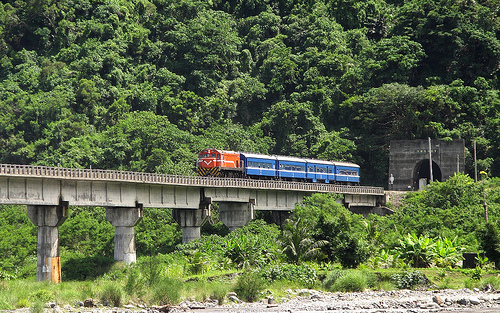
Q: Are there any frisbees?
A: No, there are no frisbees.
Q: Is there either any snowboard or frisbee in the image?
A: No, there are no frisbees or snowboards.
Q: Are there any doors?
A: Yes, there is a door.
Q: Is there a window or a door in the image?
A: Yes, there is a door.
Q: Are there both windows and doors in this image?
A: Yes, there are both a door and a window.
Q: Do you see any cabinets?
A: No, there are no cabinets.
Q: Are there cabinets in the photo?
A: No, there are no cabinets.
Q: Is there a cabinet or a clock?
A: No, there are no cabinets or clocks.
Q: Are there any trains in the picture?
A: Yes, there is a train.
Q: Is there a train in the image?
A: Yes, there is a train.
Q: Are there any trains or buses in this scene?
A: Yes, there is a train.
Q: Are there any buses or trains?
A: Yes, there is a train.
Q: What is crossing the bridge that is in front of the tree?
A: The train is crossing the bridge.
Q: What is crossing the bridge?
A: The train is crossing the bridge.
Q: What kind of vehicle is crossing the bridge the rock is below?
A: The vehicle is a train.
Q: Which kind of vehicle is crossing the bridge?
A: The vehicle is a train.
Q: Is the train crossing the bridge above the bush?
A: Yes, the train is crossing the bridge.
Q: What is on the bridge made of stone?
A: The train is on the bridge.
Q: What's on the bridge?
A: The train is on the bridge.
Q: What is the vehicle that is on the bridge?
A: The vehicle is a train.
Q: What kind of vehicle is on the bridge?
A: The vehicle is a train.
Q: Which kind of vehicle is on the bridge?
A: The vehicle is a train.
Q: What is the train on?
A: The train is on the bridge.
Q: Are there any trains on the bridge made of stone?
A: Yes, there is a train on the bridge.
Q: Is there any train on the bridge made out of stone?
A: Yes, there is a train on the bridge.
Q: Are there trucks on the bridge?
A: No, there is a train on the bridge.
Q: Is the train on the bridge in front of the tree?
A: Yes, the train is on the bridge.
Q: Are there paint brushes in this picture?
A: No, there are no paint brushes.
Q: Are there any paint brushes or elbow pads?
A: No, there are no paint brushes or elbow pads.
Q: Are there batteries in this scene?
A: No, there are no batteries.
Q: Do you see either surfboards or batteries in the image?
A: No, there are no batteries or surfboards.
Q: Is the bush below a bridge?
A: Yes, the bush is below a bridge.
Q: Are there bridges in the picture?
A: Yes, there is a bridge.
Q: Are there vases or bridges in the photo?
A: Yes, there is a bridge.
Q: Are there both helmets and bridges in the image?
A: No, there is a bridge but no helmets.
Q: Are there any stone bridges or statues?
A: Yes, there is a stone bridge.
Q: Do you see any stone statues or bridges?
A: Yes, there is a stone bridge.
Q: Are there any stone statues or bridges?
A: Yes, there is a stone bridge.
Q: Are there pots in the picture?
A: No, there are no pots.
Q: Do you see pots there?
A: No, there are no pots.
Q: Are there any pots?
A: No, there are no pots.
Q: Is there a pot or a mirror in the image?
A: No, there are no pots or mirrors.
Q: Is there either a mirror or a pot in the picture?
A: No, there are no pots or mirrors.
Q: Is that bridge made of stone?
A: Yes, the bridge is made of stone.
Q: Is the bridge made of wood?
A: No, the bridge is made of stone.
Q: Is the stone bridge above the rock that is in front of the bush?
A: Yes, the bridge is above the rock.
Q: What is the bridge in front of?
A: The bridge is in front of the tree.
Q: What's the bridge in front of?
A: The bridge is in front of the tree.